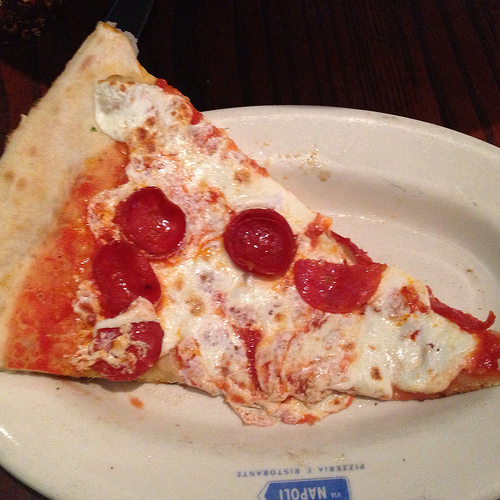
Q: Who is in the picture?
A: Nobody.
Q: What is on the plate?
A: Pizza.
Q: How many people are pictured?
A: 0.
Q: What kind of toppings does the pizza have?
A: Pepperoni.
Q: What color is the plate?
A: White.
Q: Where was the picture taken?
A: Home.